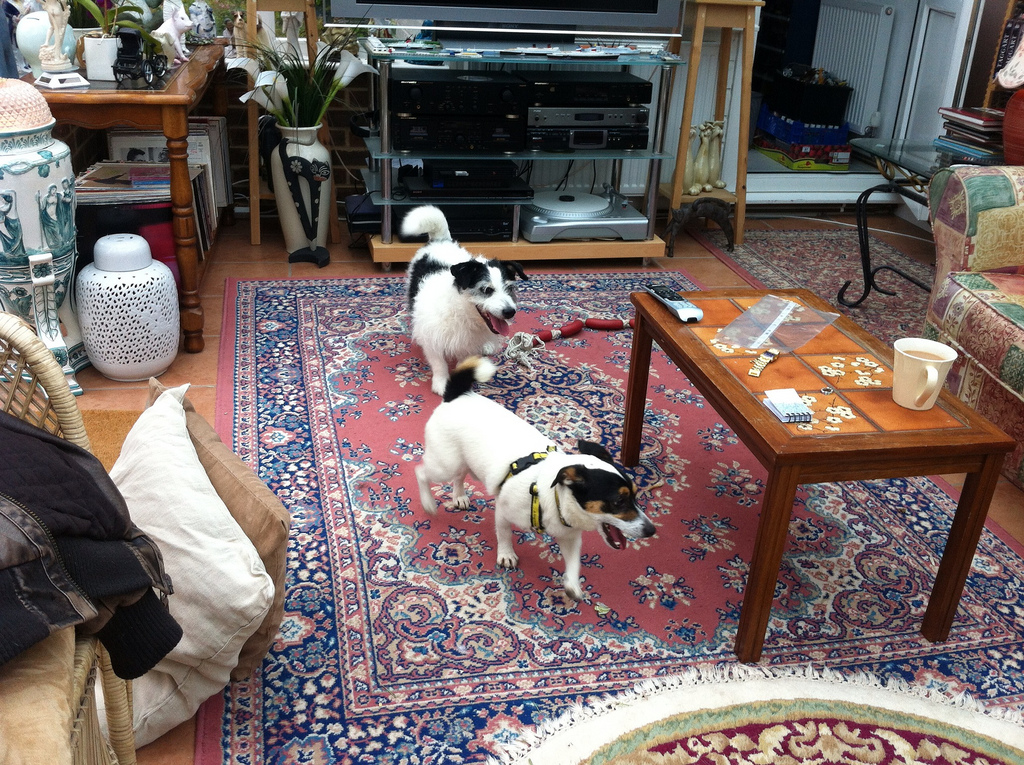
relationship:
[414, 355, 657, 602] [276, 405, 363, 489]
dog on rug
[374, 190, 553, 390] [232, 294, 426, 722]
dog on rug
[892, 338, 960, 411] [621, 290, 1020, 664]
coffee mug on coffee table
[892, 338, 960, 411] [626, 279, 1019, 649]
coffee mug on coffee table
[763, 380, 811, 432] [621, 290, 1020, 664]
notepad on coffee table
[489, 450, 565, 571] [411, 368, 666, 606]
harness on dog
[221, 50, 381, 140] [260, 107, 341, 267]
flowers in vase